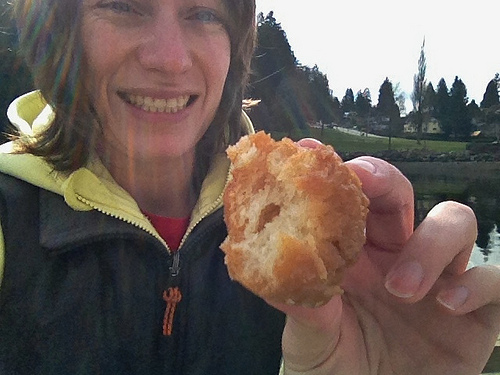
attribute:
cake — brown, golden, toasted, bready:
[218, 130, 371, 309]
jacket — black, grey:
[0, 172, 287, 374]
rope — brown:
[162, 287, 181, 334]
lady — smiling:
[1, 0, 499, 372]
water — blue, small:
[340, 155, 497, 274]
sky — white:
[253, 0, 499, 116]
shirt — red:
[139, 209, 192, 249]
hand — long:
[264, 137, 497, 373]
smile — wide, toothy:
[115, 86, 202, 123]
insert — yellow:
[0, 89, 253, 253]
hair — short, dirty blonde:
[3, 0, 262, 176]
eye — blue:
[104, 0, 133, 14]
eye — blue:
[189, 8, 215, 24]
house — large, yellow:
[400, 100, 479, 137]